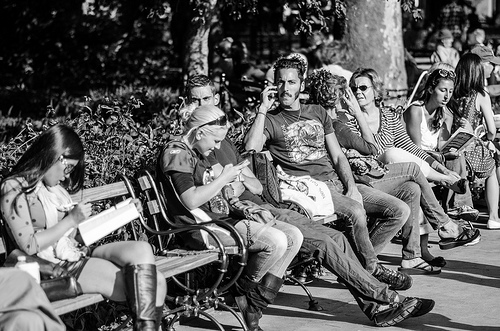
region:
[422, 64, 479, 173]
woman reading a book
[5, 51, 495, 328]
people sitting on benches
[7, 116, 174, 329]
young lady holds a book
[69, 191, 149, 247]
a book is open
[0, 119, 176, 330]
woman sits on bench with legs crossed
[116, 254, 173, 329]
boots of woman are black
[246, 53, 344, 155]
a man talking by phone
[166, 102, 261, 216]
lady looking a cell phone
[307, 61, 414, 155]
two women are talking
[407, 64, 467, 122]
woman has glasses on head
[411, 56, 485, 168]
woman is reading a book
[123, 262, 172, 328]
black knee high leather boots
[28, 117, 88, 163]
Person has dark hair.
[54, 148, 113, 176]
Glasses on person's face.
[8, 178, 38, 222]
Woman wearing polka dot shirt.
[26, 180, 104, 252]
Scarf around woman's neck.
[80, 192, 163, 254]
Woman holding book in hand.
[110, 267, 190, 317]
Woman wearing boots.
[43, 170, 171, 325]
Woman sitting on park bench.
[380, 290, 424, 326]
Person wearing dark shoes.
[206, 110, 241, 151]
Sunglasses on girl's head.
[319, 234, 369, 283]
Person wearing blue jeans.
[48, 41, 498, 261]
a group of people sitting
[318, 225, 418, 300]
leg of a person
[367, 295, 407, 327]
shoe of a person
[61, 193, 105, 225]
hand of the girl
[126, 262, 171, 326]
socks of the girl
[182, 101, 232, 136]
a small cap wearing by boy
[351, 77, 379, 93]
spectacles wearing by girl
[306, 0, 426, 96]
a part of a large tree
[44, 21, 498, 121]
a large group of trees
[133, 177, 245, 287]
a small iron divider